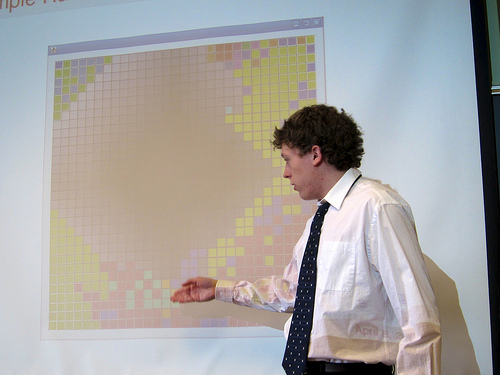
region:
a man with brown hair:
[269, 102, 365, 195]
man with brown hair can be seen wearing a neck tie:
[266, 99, 351, 374]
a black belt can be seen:
[308, 362, 391, 374]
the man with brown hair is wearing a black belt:
[270, 106, 396, 373]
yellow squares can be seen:
[240, 95, 285, 120]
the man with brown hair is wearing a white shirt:
[215, 100, 444, 372]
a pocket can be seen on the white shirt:
[320, 231, 395, 324]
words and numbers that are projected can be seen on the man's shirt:
[322, 317, 436, 354]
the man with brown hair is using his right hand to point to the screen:
[167, 102, 445, 374]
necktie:
[279, 200, 336, 373]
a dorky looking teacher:
[182, 17, 449, 373]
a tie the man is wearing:
[289, 221, 315, 365]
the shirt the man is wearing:
[278, 176, 447, 357]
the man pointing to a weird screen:
[60, 81, 318, 335]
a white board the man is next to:
[342, 18, 465, 158]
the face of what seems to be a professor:
[260, 102, 432, 228]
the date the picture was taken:
[348, 291, 431, 356]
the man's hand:
[158, 257, 256, 315]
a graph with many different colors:
[58, 66, 273, 274]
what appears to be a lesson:
[14, 12, 430, 373]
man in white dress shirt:
[216, 110, 373, 328]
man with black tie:
[251, 100, 413, 345]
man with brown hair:
[129, 133, 403, 370]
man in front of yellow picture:
[219, 99, 393, 314]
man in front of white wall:
[240, 103, 448, 368]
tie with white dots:
[276, 182, 333, 372]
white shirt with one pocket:
[265, 227, 413, 341]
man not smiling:
[254, 122, 436, 254]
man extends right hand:
[145, 145, 362, 371]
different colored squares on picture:
[46, 101, 437, 342]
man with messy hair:
[191, 77, 425, 373]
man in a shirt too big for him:
[203, 79, 486, 373]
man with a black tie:
[228, 106, 464, 366]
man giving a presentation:
[62, 23, 257, 373]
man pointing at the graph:
[55, 9, 465, 374]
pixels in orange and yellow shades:
[81, 12, 442, 365]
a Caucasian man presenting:
[181, 91, 417, 373]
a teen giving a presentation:
[138, 2, 488, 316]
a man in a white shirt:
[171, 50, 486, 348]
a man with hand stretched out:
[71, 44, 496, 373]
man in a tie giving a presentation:
[146, 87, 477, 374]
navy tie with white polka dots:
[276, 201, 367, 368]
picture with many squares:
[49, 48, 278, 335]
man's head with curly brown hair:
[263, 100, 378, 205]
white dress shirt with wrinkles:
[259, 188, 475, 370]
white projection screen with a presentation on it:
[21, 14, 388, 346]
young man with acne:
[296, 167, 346, 209]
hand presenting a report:
[165, 276, 235, 308]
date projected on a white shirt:
[343, 317, 424, 345]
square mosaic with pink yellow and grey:
[63, 66, 163, 161]